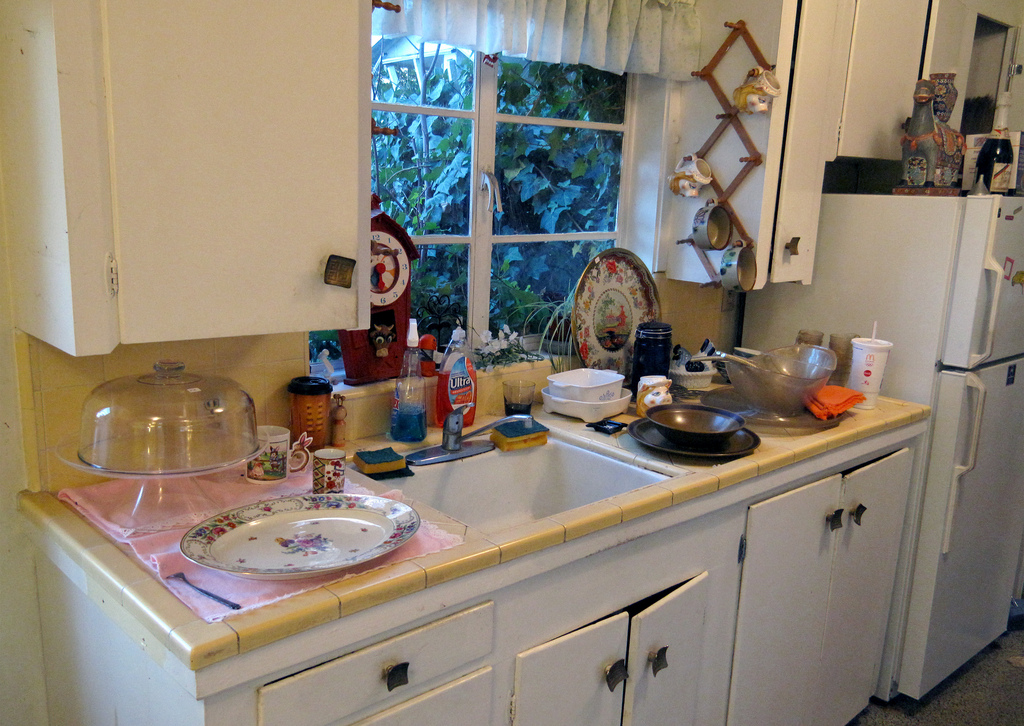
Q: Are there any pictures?
A: No, there are no pictures.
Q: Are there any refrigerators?
A: Yes, there is a refrigerator.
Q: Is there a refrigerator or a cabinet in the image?
A: Yes, there is a refrigerator.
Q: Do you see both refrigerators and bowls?
A: Yes, there are both a refrigerator and a bowl.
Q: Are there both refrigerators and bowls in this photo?
A: Yes, there are both a refrigerator and a bowl.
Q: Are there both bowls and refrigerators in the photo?
A: Yes, there are both a refrigerator and a bowl.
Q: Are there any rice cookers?
A: No, there are no rice cookers.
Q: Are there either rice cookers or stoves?
A: No, there are no rice cookers or stoves.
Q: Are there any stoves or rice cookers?
A: No, there are no rice cookers or stoves.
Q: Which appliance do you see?
A: The appliance is a refrigerator.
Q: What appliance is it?
A: The appliance is a refrigerator.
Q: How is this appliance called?
A: This is a refrigerator.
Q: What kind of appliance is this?
A: This is a refrigerator.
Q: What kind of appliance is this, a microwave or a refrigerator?
A: This is a refrigerator.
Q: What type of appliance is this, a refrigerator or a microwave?
A: This is a refrigerator.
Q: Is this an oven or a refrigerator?
A: This is a refrigerator.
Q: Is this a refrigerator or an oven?
A: This is a refrigerator.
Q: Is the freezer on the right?
A: Yes, the freezer is on the right of the image.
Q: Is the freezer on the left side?
A: No, the freezer is on the right of the image.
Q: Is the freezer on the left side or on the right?
A: The freezer is on the right of the image.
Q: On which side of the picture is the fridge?
A: The fridge is on the right of the image.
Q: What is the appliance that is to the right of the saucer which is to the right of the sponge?
A: The appliance is a refrigerator.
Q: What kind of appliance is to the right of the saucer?
A: The appliance is a refrigerator.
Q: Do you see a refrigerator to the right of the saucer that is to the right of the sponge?
A: Yes, there is a refrigerator to the right of the saucer.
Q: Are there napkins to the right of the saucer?
A: No, there is a refrigerator to the right of the saucer.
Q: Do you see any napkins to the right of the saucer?
A: No, there is a refrigerator to the right of the saucer.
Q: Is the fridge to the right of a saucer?
A: Yes, the fridge is to the right of a saucer.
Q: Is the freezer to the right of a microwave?
A: No, the freezer is to the right of a saucer.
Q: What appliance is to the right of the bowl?
A: The appliance is a refrigerator.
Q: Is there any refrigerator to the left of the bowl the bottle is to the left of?
A: No, the refrigerator is to the right of the bowl.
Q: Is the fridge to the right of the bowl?
A: Yes, the fridge is to the right of the bowl.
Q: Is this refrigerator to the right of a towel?
A: No, the refrigerator is to the right of the bowl.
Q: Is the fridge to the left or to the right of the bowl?
A: The fridge is to the right of the bowl.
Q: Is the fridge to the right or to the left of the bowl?
A: The fridge is to the right of the bowl.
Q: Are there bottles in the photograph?
A: Yes, there is a bottle.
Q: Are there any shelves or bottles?
A: Yes, there is a bottle.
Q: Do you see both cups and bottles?
A: Yes, there are both a bottle and a cup.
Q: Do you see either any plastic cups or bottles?
A: Yes, there is a plastic bottle.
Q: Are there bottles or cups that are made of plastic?
A: Yes, the bottle is made of plastic.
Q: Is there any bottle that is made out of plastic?
A: Yes, there is a bottle that is made of plastic.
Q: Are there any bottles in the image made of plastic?
A: Yes, there is a bottle that is made of plastic.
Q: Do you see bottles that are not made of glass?
A: Yes, there is a bottle that is made of plastic.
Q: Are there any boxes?
A: No, there are no boxes.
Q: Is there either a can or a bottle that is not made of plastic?
A: No, there is a bottle but it is made of plastic.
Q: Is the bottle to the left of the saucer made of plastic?
A: Yes, the bottle is made of plastic.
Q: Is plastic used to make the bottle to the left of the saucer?
A: Yes, the bottle is made of plastic.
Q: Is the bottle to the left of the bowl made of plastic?
A: Yes, the bottle is made of plastic.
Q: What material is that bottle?
A: The bottle is made of plastic.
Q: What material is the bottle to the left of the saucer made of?
A: The bottle is made of plastic.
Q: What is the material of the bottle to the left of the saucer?
A: The bottle is made of plastic.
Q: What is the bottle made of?
A: The bottle is made of plastic.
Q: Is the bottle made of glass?
A: No, the bottle is made of plastic.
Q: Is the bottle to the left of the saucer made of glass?
A: No, the bottle is made of plastic.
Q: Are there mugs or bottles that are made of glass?
A: No, there is a bottle but it is made of plastic.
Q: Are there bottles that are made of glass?
A: No, there is a bottle but it is made of plastic.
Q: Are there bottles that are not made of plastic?
A: No, there is a bottle but it is made of plastic.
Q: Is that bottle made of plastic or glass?
A: The bottle is made of plastic.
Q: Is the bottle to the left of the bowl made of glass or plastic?
A: The bottle is made of plastic.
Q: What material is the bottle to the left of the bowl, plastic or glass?
A: The bottle is made of plastic.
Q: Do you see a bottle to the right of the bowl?
A: No, the bottle is to the left of the bowl.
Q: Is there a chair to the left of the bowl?
A: No, there is a bottle to the left of the bowl.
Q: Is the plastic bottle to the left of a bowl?
A: Yes, the bottle is to the left of a bowl.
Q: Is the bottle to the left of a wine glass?
A: No, the bottle is to the left of a bowl.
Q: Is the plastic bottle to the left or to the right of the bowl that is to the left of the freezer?
A: The bottle is to the left of the bowl.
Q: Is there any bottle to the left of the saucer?
A: Yes, there is a bottle to the left of the saucer.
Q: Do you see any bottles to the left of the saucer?
A: Yes, there is a bottle to the left of the saucer.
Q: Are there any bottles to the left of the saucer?
A: Yes, there is a bottle to the left of the saucer.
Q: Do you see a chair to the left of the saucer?
A: No, there is a bottle to the left of the saucer.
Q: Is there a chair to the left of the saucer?
A: No, there is a bottle to the left of the saucer.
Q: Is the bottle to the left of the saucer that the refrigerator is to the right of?
A: Yes, the bottle is to the left of the saucer.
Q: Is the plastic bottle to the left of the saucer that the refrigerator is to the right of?
A: Yes, the bottle is to the left of the saucer.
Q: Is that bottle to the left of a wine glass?
A: No, the bottle is to the left of the saucer.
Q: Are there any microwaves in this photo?
A: No, there are no microwaves.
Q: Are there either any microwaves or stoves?
A: No, there are no microwaves or stoves.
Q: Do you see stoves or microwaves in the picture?
A: No, there are no microwaves or stoves.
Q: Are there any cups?
A: Yes, there is a cup.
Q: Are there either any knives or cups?
A: Yes, there is a cup.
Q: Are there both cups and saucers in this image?
A: Yes, there are both a cup and a saucer.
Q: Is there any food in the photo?
A: No, there is no food.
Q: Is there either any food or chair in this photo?
A: No, there are no food or chairs.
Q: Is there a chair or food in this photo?
A: No, there are no food or chairs.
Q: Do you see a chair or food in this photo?
A: No, there are no food or chairs.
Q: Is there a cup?
A: Yes, there is a cup.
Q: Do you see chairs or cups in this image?
A: Yes, there is a cup.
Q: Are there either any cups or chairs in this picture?
A: Yes, there is a cup.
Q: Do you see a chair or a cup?
A: Yes, there is a cup.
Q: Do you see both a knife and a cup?
A: No, there is a cup but no knives.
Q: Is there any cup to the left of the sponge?
A: Yes, there is a cup to the left of the sponge.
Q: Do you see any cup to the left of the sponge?
A: Yes, there is a cup to the left of the sponge.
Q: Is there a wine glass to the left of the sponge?
A: No, there is a cup to the left of the sponge.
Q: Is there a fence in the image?
A: No, there are no fences.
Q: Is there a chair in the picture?
A: No, there are no chairs.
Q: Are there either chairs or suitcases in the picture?
A: No, there are no chairs or suitcases.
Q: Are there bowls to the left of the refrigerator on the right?
A: Yes, there is a bowl to the left of the freezer.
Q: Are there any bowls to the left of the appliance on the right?
A: Yes, there is a bowl to the left of the freezer.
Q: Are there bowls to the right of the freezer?
A: No, the bowl is to the left of the freezer.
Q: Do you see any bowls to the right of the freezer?
A: No, the bowl is to the left of the freezer.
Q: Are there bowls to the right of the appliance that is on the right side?
A: No, the bowl is to the left of the freezer.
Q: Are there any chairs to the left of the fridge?
A: No, there is a bowl to the left of the fridge.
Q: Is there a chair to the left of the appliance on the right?
A: No, there is a bowl to the left of the fridge.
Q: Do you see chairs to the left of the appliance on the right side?
A: No, there is a bowl to the left of the fridge.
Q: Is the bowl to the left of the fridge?
A: Yes, the bowl is to the left of the fridge.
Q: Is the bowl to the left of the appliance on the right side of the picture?
A: Yes, the bowl is to the left of the fridge.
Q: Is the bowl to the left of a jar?
A: No, the bowl is to the left of the fridge.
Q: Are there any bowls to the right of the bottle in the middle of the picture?
A: Yes, there is a bowl to the right of the bottle.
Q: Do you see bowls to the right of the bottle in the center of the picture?
A: Yes, there is a bowl to the right of the bottle.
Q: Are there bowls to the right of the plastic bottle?
A: Yes, there is a bowl to the right of the bottle.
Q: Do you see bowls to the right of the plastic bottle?
A: Yes, there is a bowl to the right of the bottle.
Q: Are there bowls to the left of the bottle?
A: No, the bowl is to the right of the bottle.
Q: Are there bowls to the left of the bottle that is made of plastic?
A: No, the bowl is to the right of the bottle.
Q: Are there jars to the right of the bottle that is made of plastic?
A: No, there is a bowl to the right of the bottle.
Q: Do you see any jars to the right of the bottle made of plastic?
A: No, there is a bowl to the right of the bottle.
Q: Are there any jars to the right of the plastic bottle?
A: No, there is a bowl to the right of the bottle.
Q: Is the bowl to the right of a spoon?
A: No, the bowl is to the right of the bottle.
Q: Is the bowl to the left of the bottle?
A: No, the bowl is to the right of the bottle.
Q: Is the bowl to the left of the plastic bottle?
A: No, the bowl is to the right of the bottle.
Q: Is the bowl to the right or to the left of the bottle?
A: The bowl is to the right of the bottle.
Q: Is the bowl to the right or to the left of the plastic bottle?
A: The bowl is to the right of the bottle.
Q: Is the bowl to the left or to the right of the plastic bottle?
A: The bowl is to the right of the bottle.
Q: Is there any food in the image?
A: No, there is no food.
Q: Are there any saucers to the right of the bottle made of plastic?
A: Yes, there is a saucer to the right of the bottle.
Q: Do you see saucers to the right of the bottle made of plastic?
A: Yes, there is a saucer to the right of the bottle.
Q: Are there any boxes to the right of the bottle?
A: No, there is a saucer to the right of the bottle.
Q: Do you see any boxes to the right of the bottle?
A: No, there is a saucer to the right of the bottle.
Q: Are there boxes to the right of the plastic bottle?
A: No, there is a saucer to the right of the bottle.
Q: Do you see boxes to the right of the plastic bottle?
A: No, there is a saucer to the right of the bottle.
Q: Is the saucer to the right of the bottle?
A: Yes, the saucer is to the right of the bottle.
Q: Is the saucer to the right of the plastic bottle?
A: Yes, the saucer is to the right of the bottle.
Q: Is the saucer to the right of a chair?
A: No, the saucer is to the right of the bottle.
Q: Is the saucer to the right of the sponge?
A: Yes, the saucer is to the right of the sponge.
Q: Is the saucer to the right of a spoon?
A: No, the saucer is to the right of the sponge.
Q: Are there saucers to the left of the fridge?
A: Yes, there is a saucer to the left of the fridge.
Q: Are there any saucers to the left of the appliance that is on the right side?
A: Yes, there is a saucer to the left of the fridge.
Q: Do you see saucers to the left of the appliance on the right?
A: Yes, there is a saucer to the left of the fridge.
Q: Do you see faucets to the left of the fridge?
A: No, there is a saucer to the left of the fridge.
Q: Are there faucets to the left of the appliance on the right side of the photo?
A: No, there is a saucer to the left of the fridge.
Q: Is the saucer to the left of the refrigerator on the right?
A: Yes, the saucer is to the left of the fridge.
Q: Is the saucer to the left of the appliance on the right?
A: Yes, the saucer is to the left of the fridge.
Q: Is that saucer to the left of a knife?
A: No, the saucer is to the left of the fridge.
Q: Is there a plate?
A: Yes, there is a plate.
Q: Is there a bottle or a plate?
A: Yes, there is a plate.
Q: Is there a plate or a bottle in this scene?
A: Yes, there is a plate.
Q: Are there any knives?
A: No, there are no knives.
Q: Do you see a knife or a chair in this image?
A: No, there are no knives or chairs.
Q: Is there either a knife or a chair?
A: No, there are no knives or chairs.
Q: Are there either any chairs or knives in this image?
A: No, there are no knives or chairs.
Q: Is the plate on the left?
A: Yes, the plate is on the left of the image.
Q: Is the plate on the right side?
A: No, the plate is on the left of the image.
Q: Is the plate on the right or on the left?
A: The plate is on the left of the image.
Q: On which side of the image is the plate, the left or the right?
A: The plate is on the left of the image.